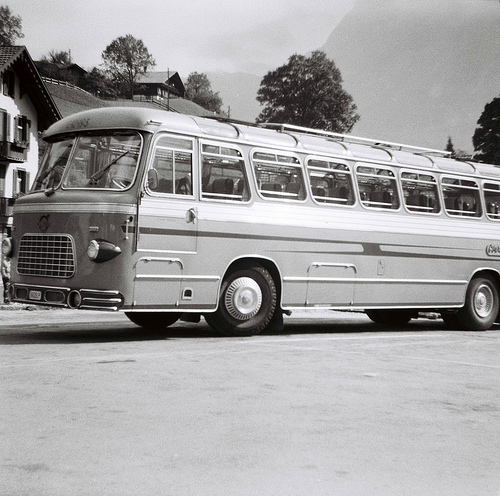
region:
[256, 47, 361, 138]
A tall tree in the background.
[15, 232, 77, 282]
The front grill on the buss.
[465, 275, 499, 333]
The rear will on the bus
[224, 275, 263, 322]
The hub cap on the bus.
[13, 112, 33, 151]
A window on the tall house.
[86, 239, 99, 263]
A headlight on the bus.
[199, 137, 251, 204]
A side window on the bus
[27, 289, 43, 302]
The front license plate on the bus.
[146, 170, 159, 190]
Side mirror to the bus.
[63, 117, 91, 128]
The number of the bus.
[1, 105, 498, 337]
large old bus on road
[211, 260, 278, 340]
round black tire of bus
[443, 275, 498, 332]
round black tire of bus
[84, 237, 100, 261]
headlight on front of bus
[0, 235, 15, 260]
headlight on front of bus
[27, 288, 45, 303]
license plate on front of bus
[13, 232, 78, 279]
grill on front of bus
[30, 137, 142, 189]
large windshield on front of bus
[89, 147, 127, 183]
black windshield wiper on bus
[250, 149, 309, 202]
window on side of bus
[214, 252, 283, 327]
The tire is black.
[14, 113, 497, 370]
The bus is on the street.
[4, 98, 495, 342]
The bus is by the house.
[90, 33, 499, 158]
The trees are leafy.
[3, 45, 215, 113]
The roof is brown.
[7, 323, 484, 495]
The street is gray.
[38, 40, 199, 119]
The house is on the hill.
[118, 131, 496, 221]
The windows are open.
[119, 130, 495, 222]
The windows are on the side of the bus.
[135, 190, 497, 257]
The bus has a white stripe.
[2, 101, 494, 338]
bus on a street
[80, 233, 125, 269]
front headlight on a bus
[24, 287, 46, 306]
front licence plate on a vehicle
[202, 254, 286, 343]
front wheel on a vehicle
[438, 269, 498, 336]
rear wheel on a vehicle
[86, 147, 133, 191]
windshield wiper on a vehicle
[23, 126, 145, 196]
front windshield on a vehicle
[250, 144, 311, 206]
side window on a vehicle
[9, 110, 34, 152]
window on a building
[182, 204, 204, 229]
door handle on a vehicle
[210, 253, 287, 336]
black tire of old bus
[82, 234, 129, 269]
left headlight of old bus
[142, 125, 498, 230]
windows along the left side of the bus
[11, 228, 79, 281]
grille on the front of the bus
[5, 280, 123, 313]
chrome bumper on the front of the bus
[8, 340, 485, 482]
pavement of the street the bus is parked on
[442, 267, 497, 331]
rear tires and wheels of the old bus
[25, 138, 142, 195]
front windshield of the old bus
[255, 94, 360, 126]
tree with leaves in the background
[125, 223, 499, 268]
pin striping on the side of the bus